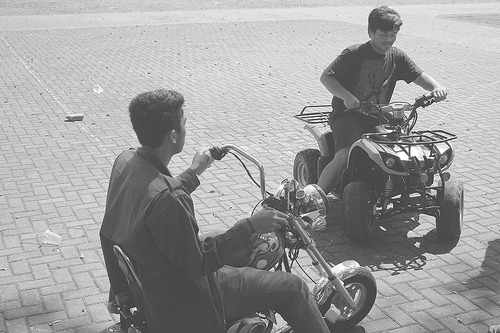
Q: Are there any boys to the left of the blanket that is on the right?
A: Yes, there is a boy to the left of the blanket.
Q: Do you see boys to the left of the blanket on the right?
A: Yes, there is a boy to the left of the blanket.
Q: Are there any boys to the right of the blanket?
A: No, the boy is to the left of the blanket.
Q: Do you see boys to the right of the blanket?
A: No, the boy is to the left of the blanket.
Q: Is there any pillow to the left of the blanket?
A: No, there is a boy to the left of the blanket.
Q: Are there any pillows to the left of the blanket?
A: No, there is a boy to the left of the blanket.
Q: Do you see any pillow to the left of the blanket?
A: No, there is a boy to the left of the blanket.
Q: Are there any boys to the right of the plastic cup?
A: Yes, there is a boy to the right of the cup.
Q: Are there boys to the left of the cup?
A: No, the boy is to the right of the cup.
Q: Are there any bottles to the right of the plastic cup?
A: No, there is a boy to the right of the cup.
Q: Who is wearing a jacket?
A: The boy is wearing a jacket.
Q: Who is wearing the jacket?
A: The boy is wearing a jacket.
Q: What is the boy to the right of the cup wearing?
A: The boy is wearing a jacket.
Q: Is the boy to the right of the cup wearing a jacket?
A: Yes, the boy is wearing a jacket.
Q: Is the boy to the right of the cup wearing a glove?
A: No, the boy is wearing a jacket.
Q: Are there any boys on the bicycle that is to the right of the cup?
A: Yes, there is a boy on the bicycle.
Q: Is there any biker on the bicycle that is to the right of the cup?
A: No, there is a boy on the bicycle.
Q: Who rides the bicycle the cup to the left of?
A: The boy rides the bicycle.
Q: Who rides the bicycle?
A: The boy rides the bicycle.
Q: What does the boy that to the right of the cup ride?
A: The boy rides the bicycle.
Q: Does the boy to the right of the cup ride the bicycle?
A: Yes, the boy rides the bicycle.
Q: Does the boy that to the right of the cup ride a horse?
A: No, the boy rides the bicycle.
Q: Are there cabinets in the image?
A: No, there are no cabinets.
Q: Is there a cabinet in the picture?
A: No, there are no cabinets.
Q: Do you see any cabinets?
A: No, there are no cabinets.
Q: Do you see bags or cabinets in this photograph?
A: No, there are no cabinets or bags.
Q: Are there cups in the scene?
A: Yes, there is a cup.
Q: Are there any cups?
A: Yes, there is a cup.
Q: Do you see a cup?
A: Yes, there is a cup.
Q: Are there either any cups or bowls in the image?
A: Yes, there is a cup.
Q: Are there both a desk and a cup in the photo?
A: No, there is a cup but no desks.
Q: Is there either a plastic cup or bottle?
A: Yes, there is a plastic cup.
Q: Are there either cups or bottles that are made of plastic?
A: Yes, the cup is made of plastic.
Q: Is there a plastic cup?
A: Yes, there is a cup that is made of plastic.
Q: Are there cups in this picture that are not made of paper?
A: Yes, there is a cup that is made of plastic.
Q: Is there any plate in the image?
A: No, there are no plates.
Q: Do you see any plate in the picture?
A: No, there are no plates.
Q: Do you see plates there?
A: No, there are no plates.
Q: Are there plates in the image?
A: No, there are no plates.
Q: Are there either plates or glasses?
A: No, there are no plates or glasses.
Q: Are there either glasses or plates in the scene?
A: No, there are no plates or glasses.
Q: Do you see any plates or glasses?
A: No, there are no plates or glasses.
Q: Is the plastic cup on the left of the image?
A: Yes, the cup is on the left of the image.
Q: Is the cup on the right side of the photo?
A: No, the cup is on the left of the image.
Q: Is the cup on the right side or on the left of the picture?
A: The cup is on the left of the image.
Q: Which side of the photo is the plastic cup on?
A: The cup is on the left of the image.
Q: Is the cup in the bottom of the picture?
A: Yes, the cup is in the bottom of the image.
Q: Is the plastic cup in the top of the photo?
A: No, the cup is in the bottom of the image.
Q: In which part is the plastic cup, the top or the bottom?
A: The cup is in the bottom of the image.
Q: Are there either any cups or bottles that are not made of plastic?
A: No, there is a cup but it is made of plastic.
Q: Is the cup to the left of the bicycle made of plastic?
A: Yes, the cup is made of plastic.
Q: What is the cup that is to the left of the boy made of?
A: The cup is made of plastic.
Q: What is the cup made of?
A: The cup is made of plastic.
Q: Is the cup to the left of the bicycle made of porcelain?
A: No, the cup is made of plastic.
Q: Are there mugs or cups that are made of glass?
A: No, there is a cup but it is made of plastic.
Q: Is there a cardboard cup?
A: No, there is a cup but it is made of plastic.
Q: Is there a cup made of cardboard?
A: No, there is a cup but it is made of plastic.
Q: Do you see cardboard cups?
A: No, there is a cup but it is made of plastic.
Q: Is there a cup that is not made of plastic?
A: No, there is a cup but it is made of plastic.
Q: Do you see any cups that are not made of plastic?
A: No, there is a cup but it is made of plastic.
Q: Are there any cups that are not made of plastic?
A: No, there is a cup but it is made of plastic.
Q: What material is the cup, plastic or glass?
A: The cup is made of plastic.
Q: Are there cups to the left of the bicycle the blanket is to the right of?
A: Yes, there is a cup to the left of the bicycle.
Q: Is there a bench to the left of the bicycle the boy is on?
A: No, there is a cup to the left of the bicycle.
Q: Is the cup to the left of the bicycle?
A: Yes, the cup is to the left of the bicycle.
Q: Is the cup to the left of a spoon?
A: No, the cup is to the left of the bicycle.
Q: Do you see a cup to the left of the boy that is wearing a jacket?
A: Yes, there is a cup to the left of the boy.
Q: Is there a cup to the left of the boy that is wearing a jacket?
A: Yes, there is a cup to the left of the boy.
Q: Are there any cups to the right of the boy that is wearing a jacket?
A: No, the cup is to the left of the boy.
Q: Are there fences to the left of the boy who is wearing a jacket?
A: No, there is a cup to the left of the boy.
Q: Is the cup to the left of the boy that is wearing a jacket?
A: Yes, the cup is to the left of the boy.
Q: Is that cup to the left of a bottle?
A: No, the cup is to the left of the boy.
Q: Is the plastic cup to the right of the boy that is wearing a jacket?
A: No, the cup is to the left of the boy.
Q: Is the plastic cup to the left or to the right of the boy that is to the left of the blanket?
A: The cup is to the left of the boy.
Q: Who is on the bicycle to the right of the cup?
A: The boy is on the bicycle.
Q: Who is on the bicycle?
A: The boy is on the bicycle.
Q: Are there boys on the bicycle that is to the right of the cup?
A: Yes, there is a boy on the bicycle.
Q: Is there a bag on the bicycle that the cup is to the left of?
A: No, there is a boy on the bicycle.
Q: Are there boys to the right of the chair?
A: Yes, there is a boy to the right of the chair.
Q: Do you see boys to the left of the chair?
A: No, the boy is to the right of the chair.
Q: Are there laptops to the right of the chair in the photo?
A: No, there is a boy to the right of the chair.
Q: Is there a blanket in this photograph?
A: Yes, there is a blanket.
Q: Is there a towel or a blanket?
A: Yes, there is a blanket.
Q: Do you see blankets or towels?
A: Yes, there is a blanket.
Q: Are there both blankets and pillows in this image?
A: No, there is a blanket but no pillows.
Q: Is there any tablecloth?
A: No, there are no tablecloths.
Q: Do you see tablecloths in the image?
A: No, there are no tablecloths.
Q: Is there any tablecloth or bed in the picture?
A: No, there are no tablecloths or beds.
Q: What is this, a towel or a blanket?
A: This is a blanket.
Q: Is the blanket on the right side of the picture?
A: Yes, the blanket is on the right of the image.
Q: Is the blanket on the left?
A: No, the blanket is on the right of the image.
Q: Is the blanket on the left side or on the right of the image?
A: The blanket is on the right of the image.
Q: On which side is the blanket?
A: The blanket is on the right of the image.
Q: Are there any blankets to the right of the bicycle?
A: Yes, there is a blanket to the right of the bicycle.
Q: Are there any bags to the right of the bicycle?
A: No, there is a blanket to the right of the bicycle.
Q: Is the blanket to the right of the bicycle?
A: Yes, the blanket is to the right of the bicycle.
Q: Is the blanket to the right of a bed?
A: No, the blanket is to the right of the bicycle.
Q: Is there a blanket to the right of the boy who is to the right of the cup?
A: Yes, there is a blanket to the right of the boy.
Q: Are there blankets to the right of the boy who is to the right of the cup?
A: Yes, there is a blanket to the right of the boy.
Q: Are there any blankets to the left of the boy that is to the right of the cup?
A: No, the blanket is to the right of the boy.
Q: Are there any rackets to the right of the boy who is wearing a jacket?
A: No, there is a blanket to the right of the boy.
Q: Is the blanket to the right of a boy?
A: Yes, the blanket is to the right of a boy.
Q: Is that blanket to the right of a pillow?
A: No, the blanket is to the right of a boy.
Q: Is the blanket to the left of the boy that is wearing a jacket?
A: No, the blanket is to the right of the boy.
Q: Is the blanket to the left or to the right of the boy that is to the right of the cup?
A: The blanket is to the right of the boy.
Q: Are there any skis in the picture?
A: No, there are no skis.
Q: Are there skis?
A: No, there are no skis.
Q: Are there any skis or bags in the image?
A: No, there are no skis or bags.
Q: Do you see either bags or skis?
A: No, there are no skis or bags.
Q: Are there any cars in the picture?
A: No, there are no cars.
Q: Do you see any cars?
A: No, there are no cars.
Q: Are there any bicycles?
A: Yes, there is a bicycle.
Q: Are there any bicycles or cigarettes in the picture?
A: Yes, there is a bicycle.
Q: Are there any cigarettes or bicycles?
A: Yes, there is a bicycle.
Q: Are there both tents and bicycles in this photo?
A: No, there is a bicycle but no tents.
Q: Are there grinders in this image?
A: No, there are no grinders.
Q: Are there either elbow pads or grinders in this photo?
A: No, there are no grinders or elbow pads.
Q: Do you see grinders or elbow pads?
A: No, there are no grinders or elbow pads.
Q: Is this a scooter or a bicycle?
A: This is a bicycle.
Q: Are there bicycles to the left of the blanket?
A: Yes, there is a bicycle to the left of the blanket.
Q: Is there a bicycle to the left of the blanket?
A: Yes, there is a bicycle to the left of the blanket.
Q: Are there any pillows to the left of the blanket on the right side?
A: No, there is a bicycle to the left of the blanket.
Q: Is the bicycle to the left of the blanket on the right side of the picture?
A: Yes, the bicycle is to the left of the blanket.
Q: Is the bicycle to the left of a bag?
A: No, the bicycle is to the left of the blanket.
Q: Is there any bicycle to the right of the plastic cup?
A: Yes, there is a bicycle to the right of the cup.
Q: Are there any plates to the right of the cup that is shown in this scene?
A: No, there is a bicycle to the right of the cup.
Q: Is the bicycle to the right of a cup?
A: Yes, the bicycle is to the right of a cup.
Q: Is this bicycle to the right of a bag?
A: No, the bicycle is to the right of a cup.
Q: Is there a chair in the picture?
A: Yes, there is a chair.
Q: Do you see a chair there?
A: Yes, there is a chair.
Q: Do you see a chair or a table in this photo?
A: Yes, there is a chair.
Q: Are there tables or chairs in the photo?
A: Yes, there is a chair.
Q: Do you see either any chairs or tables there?
A: Yes, there is a chair.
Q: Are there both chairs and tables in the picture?
A: No, there is a chair but no tables.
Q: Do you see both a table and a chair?
A: No, there is a chair but no tables.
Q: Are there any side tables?
A: No, there are no side tables.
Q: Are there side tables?
A: No, there are no side tables.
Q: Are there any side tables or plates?
A: No, there are no side tables or plates.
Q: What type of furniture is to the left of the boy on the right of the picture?
A: The piece of furniture is a chair.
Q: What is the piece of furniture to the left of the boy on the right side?
A: The piece of furniture is a chair.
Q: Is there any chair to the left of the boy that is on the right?
A: Yes, there is a chair to the left of the boy.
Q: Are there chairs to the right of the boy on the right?
A: No, the chair is to the left of the boy.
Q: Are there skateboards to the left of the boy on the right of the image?
A: No, there is a chair to the left of the boy.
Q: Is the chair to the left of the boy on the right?
A: Yes, the chair is to the left of the boy.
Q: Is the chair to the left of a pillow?
A: No, the chair is to the left of the boy.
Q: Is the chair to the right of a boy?
A: No, the chair is to the left of a boy.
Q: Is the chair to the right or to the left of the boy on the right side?
A: The chair is to the left of the boy.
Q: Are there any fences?
A: No, there are no fences.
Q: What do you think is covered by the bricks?
A: The ground is covered by the bricks.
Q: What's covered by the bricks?
A: The ground is covered by the bricks.